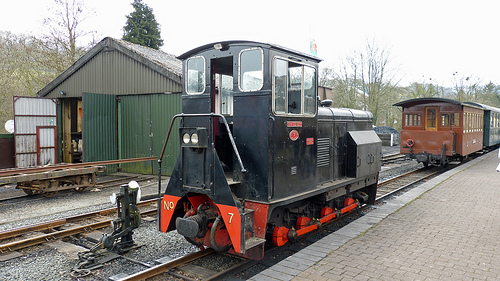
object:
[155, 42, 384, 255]
train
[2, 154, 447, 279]
track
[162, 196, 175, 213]
letters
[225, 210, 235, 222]
numbers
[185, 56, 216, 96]
windows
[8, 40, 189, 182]
building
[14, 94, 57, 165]
door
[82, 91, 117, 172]
door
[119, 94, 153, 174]
door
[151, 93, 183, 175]
door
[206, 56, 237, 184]
door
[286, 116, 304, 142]
letters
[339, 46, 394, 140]
trees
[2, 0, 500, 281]
background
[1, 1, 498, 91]
sky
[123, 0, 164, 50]
tree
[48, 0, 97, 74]
tree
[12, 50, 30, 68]
leaves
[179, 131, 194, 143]
lights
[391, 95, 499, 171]
traincar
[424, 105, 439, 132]
windows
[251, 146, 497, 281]
sidewalk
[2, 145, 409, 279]
gravel